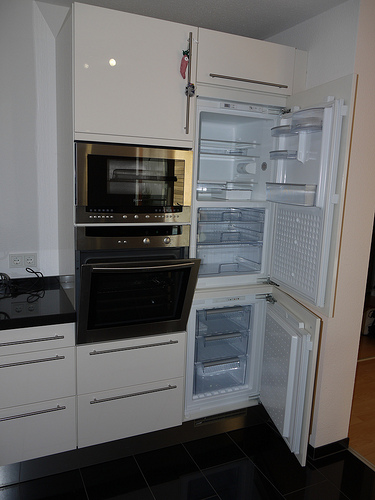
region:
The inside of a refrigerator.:
[195, 105, 266, 270]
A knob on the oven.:
[137, 230, 146, 239]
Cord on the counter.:
[0, 262, 45, 307]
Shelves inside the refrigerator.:
[198, 206, 258, 268]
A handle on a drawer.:
[85, 378, 175, 409]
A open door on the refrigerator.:
[258, 94, 348, 315]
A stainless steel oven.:
[75, 141, 195, 341]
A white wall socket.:
[5, 249, 37, 268]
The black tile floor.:
[2, 409, 370, 496]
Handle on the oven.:
[89, 260, 197, 274]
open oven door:
[76, 248, 198, 343]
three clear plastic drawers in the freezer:
[193, 306, 250, 391]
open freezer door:
[260, 291, 320, 471]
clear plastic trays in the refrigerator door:
[265, 106, 324, 213]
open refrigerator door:
[267, 68, 360, 318]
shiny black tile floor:
[0, 420, 374, 498]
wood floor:
[347, 359, 373, 472]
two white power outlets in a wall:
[6, 252, 38, 269]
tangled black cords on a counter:
[0, 265, 49, 299]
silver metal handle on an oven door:
[90, 261, 196, 271]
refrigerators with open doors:
[192, 93, 324, 464]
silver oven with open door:
[79, 239, 196, 340]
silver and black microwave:
[76, 142, 191, 226]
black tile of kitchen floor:
[13, 421, 370, 498]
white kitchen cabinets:
[2, 332, 180, 460]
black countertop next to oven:
[1, 275, 67, 326]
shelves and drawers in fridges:
[195, 120, 264, 399]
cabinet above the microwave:
[70, 8, 196, 140]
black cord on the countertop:
[5, 264, 48, 290]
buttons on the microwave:
[85, 210, 188, 221]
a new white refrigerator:
[197, 70, 352, 451]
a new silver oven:
[74, 137, 193, 336]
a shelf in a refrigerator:
[196, 204, 265, 224]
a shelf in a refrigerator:
[199, 130, 276, 146]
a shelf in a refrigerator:
[199, 166, 262, 178]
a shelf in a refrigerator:
[196, 360, 247, 389]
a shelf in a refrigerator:
[198, 333, 248, 354]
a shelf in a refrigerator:
[199, 310, 253, 328]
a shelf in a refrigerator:
[198, 223, 260, 244]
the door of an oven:
[78, 263, 197, 339]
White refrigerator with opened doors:
[182, 95, 343, 465]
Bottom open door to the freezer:
[184, 281, 320, 467]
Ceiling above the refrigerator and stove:
[72, 0, 362, 42]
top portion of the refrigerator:
[196, 96, 347, 309]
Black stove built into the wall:
[75, 223, 198, 343]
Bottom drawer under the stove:
[74, 374, 192, 447]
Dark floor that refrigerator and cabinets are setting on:
[3, 401, 371, 497]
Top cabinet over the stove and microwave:
[71, 1, 194, 147]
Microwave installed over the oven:
[73, 141, 183, 222]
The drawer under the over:
[75, 331, 185, 393]